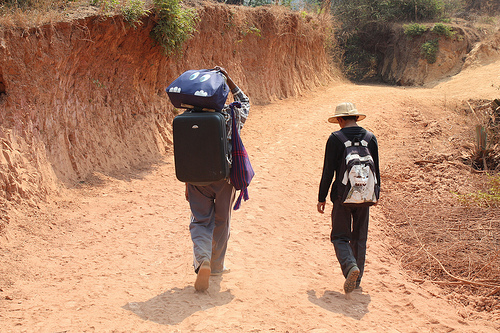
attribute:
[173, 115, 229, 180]
suitcase — black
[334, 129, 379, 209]
bag — black, white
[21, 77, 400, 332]
pathway — dirt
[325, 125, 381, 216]
backpack — white, black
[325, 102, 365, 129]
hat — tan, straw